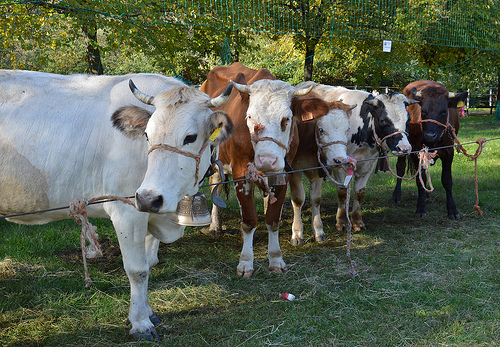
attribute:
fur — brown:
[202, 64, 233, 100]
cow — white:
[0, 69, 234, 337]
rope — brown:
[463, 138, 483, 218]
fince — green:
[2, 1, 497, 53]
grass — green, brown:
[8, 226, 492, 342]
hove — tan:
[128, 310, 163, 342]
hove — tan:
[236, 262, 290, 279]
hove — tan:
[291, 230, 328, 247]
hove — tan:
[414, 206, 462, 219]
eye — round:
[182, 132, 199, 146]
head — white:
[117, 87, 223, 214]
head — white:
[235, 79, 298, 170]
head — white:
[317, 103, 350, 170]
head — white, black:
[374, 96, 412, 158]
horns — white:
[127, 80, 236, 106]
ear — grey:
[112, 104, 154, 138]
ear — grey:
[209, 110, 233, 144]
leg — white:
[99, 184, 162, 335]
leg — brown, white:
[233, 177, 259, 278]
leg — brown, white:
[266, 176, 290, 275]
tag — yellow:
[211, 122, 224, 142]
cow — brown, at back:
[397, 79, 462, 219]